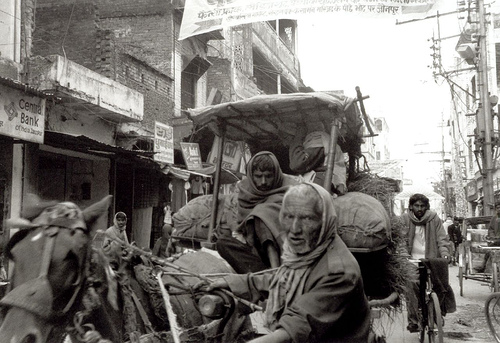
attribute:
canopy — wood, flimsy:
[182, 92, 382, 142]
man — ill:
[215, 140, 297, 231]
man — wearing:
[394, 194, 451, 331]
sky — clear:
[373, 42, 421, 141]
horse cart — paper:
[5, 86, 426, 331]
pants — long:
[408, 260, 447, 324]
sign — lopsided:
[180, 142, 205, 170]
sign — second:
[153, 120, 173, 164]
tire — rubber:
[428, 290, 443, 341]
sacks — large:
[334, 190, 396, 247]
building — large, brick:
[23, 0, 175, 200]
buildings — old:
[36, 23, 430, 292]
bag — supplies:
[168, 191, 229, 242]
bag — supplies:
[329, 183, 390, 250]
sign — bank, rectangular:
[0, 81, 47, 146]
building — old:
[1, 1, 359, 239]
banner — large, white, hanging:
[185, 0, 427, 60]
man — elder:
[284, 175, 359, 315]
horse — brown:
[8, 200, 248, 322]